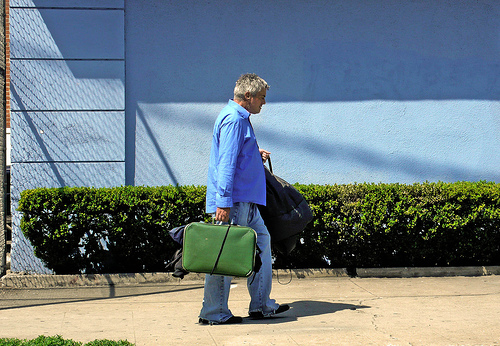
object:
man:
[197, 72, 291, 325]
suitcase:
[181, 218, 261, 279]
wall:
[272, 15, 476, 168]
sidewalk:
[28, 290, 371, 331]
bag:
[261, 153, 314, 244]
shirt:
[206, 100, 269, 213]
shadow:
[160, 34, 187, 96]